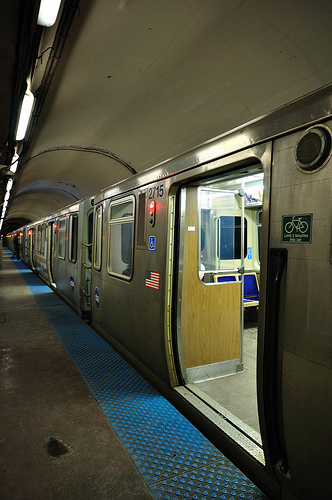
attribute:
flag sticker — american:
[137, 266, 175, 301]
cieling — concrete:
[102, 23, 253, 138]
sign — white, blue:
[148, 234, 157, 251]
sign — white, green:
[280, 210, 312, 242]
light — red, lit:
[147, 202, 154, 210]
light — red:
[137, 191, 199, 255]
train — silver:
[56, 144, 197, 327]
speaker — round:
[291, 123, 330, 175]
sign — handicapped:
[146, 234, 161, 254]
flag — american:
[142, 267, 163, 293]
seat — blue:
[213, 273, 271, 312]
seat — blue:
[230, 264, 256, 301]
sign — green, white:
[279, 211, 315, 244]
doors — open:
[163, 152, 269, 463]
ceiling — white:
[0, 0, 331, 237]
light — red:
[147, 196, 156, 215]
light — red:
[53, 223, 59, 230]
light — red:
[26, 228, 32, 235]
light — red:
[17, 230, 25, 238]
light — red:
[12, 232, 18, 237]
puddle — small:
[44, 436, 69, 455]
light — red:
[53, 221, 62, 235]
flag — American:
[144, 266, 159, 289]